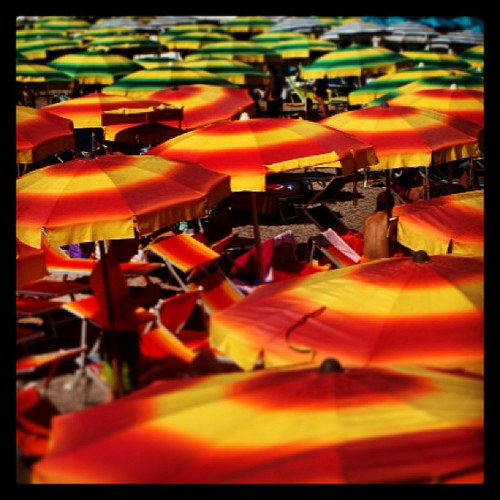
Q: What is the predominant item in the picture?
A: An umbrella.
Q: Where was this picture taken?
A: At the beach.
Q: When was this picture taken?
A: In the daytime.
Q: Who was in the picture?
A: Beachgoers.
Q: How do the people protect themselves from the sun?
A: With umbrellas.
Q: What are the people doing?
A: Enjoying the beach.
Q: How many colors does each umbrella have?
A: Two.